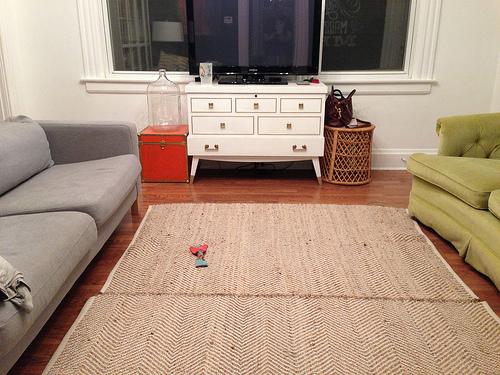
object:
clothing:
[0, 256, 34, 314]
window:
[104, 1, 193, 73]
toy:
[189, 244, 209, 268]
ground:
[0, 150, 500, 375]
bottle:
[146, 68, 182, 132]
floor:
[0, 167, 499, 375]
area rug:
[42, 202, 499, 374]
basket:
[322, 117, 377, 186]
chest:
[137, 124, 190, 184]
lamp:
[151, 20, 183, 42]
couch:
[0, 113, 145, 375]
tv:
[184, 0, 321, 84]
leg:
[131, 199, 139, 218]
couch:
[404, 111, 498, 291]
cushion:
[0, 154, 141, 227]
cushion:
[0, 210, 98, 365]